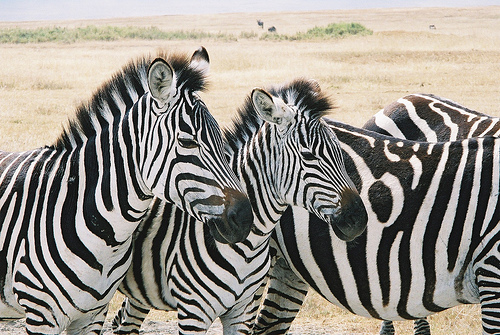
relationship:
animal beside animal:
[0, 44, 256, 335] [108, 75, 369, 334]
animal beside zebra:
[108, 75, 369, 334] [256, 93, 499, 335]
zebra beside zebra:
[256, 93, 499, 335] [354, 90, 498, 332]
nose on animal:
[225, 193, 255, 227] [0, 44, 256, 332]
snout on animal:
[327, 185, 365, 240] [116, 70, 368, 332]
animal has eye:
[116, 70, 368, 332] [300, 149, 319, 162]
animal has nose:
[0, 44, 256, 335] [199, 204, 257, 243]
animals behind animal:
[257, 18, 278, 34] [0, 44, 256, 335]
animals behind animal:
[257, 18, 278, 34] [108, 75, 369, 334]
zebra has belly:
[256, 93, 499, 335] [288, 221, 485, 325]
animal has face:
[0, 44, 256, 335] [137, 49, 257, 242]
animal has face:
[108, 75, 369, 334] [247, 77, 368, 241]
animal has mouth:
[108, 75, 369, 334] [332, 210, 374, 239]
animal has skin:
[108, 75, 369, 334] [276, 77, 332, 119]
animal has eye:
[108, 75, 369, 334] [302, 144, 318, 163]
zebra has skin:
[256, 93, 499, 335] [407, 180, 433, 318]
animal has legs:
[108, 75, 369, 334] [170, 297, 266, 329]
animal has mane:
[0, 44, 256, 335] [175, 66, 204, 91]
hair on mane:
[91, 73, 121, 93] [47, 48, 206, 152]